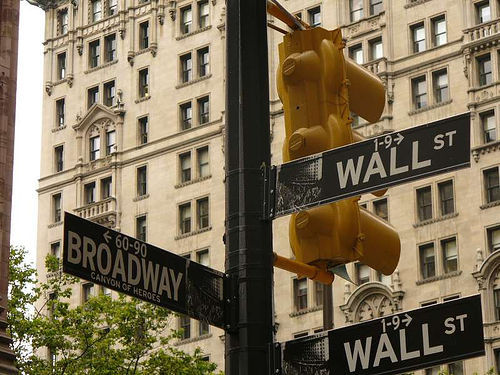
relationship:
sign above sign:
[270, 109, 477, 221] [273, 292, 490, 372]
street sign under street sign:
[270, 283, 489, 367] [264, 104, 474, 213]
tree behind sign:
[6, 242, 223, 373] [50, 182, 238, 329]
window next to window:
[410, 71, 430, 105] [436, 66, 447, 97]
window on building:
[436, 66, 447, 97] [27, 0, 497, 371]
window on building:
[410, 71, 430, 105] [27, 0, 497, 371]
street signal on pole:
[263, 0, 407, 292] [216, 0, 288, 373]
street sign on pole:
[270, 292, 486, 375] [222, 17, 300, 344]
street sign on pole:
[270, 292, 486, 375] [221, 2, 272, 373]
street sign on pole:
[270, 292, 486, 375] [209, 49, 288, 299]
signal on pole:
[280, 15, 398, 288] [210, 9, 285, 338]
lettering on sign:
[64, 233, 184, 305] [55, 208, 227, 338]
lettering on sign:
[339, 130, 464, 197] [264, 112, 474, 227]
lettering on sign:
[340, 314, 472, 372] [273, 292, 490, 372]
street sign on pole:
[270, 292, 486, 375] [226, 2, 271, 372]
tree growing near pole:
[6, 242, 223, 373] [226, 2, 270, 375]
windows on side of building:
[160, 43, 222, 268] [57, 20, 197, 229]